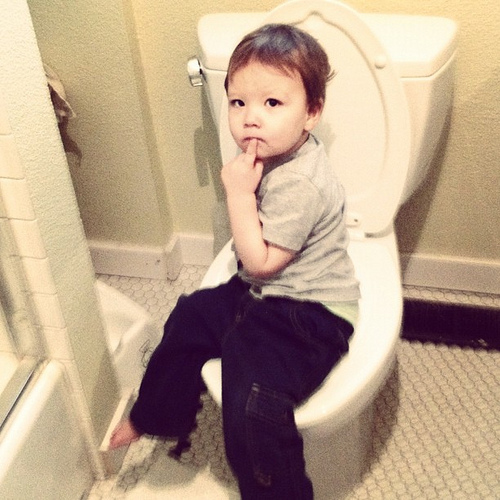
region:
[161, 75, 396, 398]
A toilet seat with a little boy on top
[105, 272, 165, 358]
A training potty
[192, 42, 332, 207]
A little boy with his finger in his mouth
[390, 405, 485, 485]
A floor comprised of small tiles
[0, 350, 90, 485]
The edge of a bathtub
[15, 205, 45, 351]
Tile lining a shower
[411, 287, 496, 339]
A vent in the floor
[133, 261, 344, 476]
Blue jeans on a little boy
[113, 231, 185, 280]
Baseboard on the bottom of a wall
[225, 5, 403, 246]
A lifted up toilet lid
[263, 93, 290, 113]
the eye of a boy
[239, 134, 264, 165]
the finger of a boy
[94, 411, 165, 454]
the foot of a boy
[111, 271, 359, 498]
a pair of black pants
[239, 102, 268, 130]
the nose of a boy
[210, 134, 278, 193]
the hand of a boy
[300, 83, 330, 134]
the ear of a boy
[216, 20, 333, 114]
the hair of a boy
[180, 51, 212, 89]
the flushing handle of the toilet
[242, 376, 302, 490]
a pocket on the pants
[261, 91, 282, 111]
the eye of the boy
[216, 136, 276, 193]
the hand of the boy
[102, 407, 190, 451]
the foot of the boy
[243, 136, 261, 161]
the finger of the boy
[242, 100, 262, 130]
the nose of the boy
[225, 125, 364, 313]
a gray tee shirt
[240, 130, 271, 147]
the mouth of the boy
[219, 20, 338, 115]
the hair of the boy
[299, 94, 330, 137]
the ear of the boy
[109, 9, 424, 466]
a child sitting on the toilet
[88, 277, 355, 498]
a pair of children's jeans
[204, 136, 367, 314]
a gray children's shirt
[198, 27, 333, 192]
a child touching his lips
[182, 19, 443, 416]
a porcelain toilet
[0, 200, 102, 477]
the corner of a bathtub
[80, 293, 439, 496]
a tiled bathroom floor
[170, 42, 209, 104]
a metal toilet flushing handle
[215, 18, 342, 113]
short brown hair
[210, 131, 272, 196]
a pale child's hand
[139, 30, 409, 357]
kid on a toilet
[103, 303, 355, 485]
pants on kid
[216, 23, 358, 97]
brown hair of kid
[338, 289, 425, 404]
white toilet rim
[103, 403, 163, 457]
bare feet of the child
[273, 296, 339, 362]
pocket on kid's pants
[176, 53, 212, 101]
handle of the toilet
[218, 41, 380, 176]
kid with finger in mouth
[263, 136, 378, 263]
gray shirt on kid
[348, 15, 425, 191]
toilet seat behind the kid